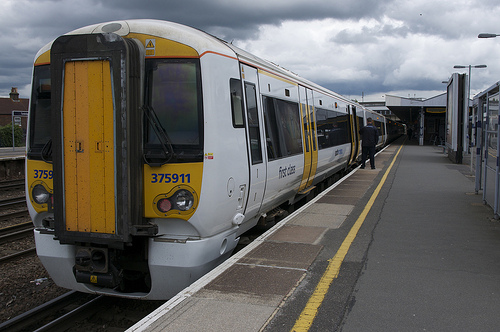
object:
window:
[262, 95, 303, 162]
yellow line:
[290, 193, 375, 332]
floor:
[307, 204, 496, 328]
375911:
[150, 172, 190, 183]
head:
[367, 117, 374, 123]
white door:
[237, 60, 272, 230]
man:
[358, 117, 379, 170]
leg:
[360, 145, 368, 169]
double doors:
[296, 83, 317, 193]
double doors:
[346, 102, 357, 164]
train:
[25, 18, 403, 303]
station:
[120, 30, 500, 332]